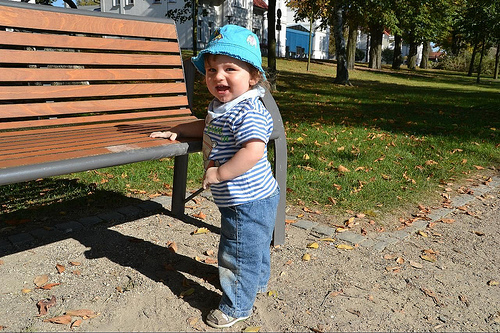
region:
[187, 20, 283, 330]
small child looking at camera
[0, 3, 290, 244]
wood and metal park bench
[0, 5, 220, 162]
brown wooden slats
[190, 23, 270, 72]
a small blue child's hat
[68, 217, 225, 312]
child's shadow on the sidewalk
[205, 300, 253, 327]
child's tiny shoe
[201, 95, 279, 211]
little striped short sleeved shirt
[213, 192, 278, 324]
pair of tiny blue jeans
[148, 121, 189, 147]
hand resting on bench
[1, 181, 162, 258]
shadow of bench on grass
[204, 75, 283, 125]
the kid is smiling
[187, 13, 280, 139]
the kid is wearing a hat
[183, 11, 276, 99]
the hat is blue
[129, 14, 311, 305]
the toddler is standing in front of the bench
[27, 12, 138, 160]
the bench is brown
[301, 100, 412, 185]
the grass is green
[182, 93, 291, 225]
the shirt is stripes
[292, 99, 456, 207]
dry leaves are on the ground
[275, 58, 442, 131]
shadows are on the ground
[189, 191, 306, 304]
the jeans are blue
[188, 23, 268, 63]
Aqua blue hat on baby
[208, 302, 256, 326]
light brown baby sandal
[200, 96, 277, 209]
Blue and white striped shirt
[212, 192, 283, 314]
Blue denim pants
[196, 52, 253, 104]
Smiling baby face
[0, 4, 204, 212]
Brown park bench with gray edges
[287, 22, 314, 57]
Large blue door on building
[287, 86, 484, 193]
Dead brown leaves in grass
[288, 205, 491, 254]
Gray bricks surrounding grass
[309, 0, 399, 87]
Leafy tree with green leaves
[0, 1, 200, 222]
wooden bench with metal trim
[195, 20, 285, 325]
little girl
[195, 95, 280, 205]
girl is wearing a blue and white striped shirt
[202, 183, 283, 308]
girl is wearing blue jeans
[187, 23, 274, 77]
girl is wearing a blue hat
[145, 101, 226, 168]
girl is resting her right hand and arm on bench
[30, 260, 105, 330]
dry leaves on the ground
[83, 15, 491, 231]
grassy area near bench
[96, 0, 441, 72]
buildings in the background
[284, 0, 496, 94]
trees in grassy area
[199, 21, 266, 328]
this is a small child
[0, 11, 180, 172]
this is a bench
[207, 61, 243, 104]
the small child is smiling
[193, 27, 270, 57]
it is wearing a hat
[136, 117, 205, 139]
its hand is on the bench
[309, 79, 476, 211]
the grass are behind the small child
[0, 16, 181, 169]
the bench is brown in color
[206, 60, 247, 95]
the childs skin color is white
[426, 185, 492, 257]
dry leaves are on the ground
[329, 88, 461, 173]
the grass is green